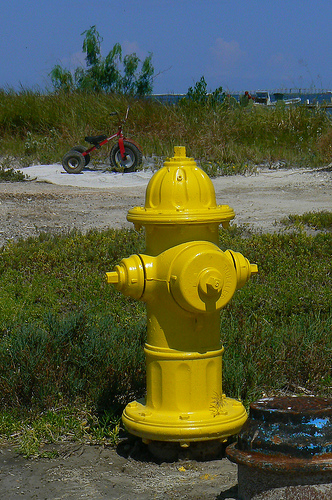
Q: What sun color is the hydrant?
A: Yellow.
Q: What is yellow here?
A: Fire hydrant.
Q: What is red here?
A: A bicycle.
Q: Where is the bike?
A: On the dirt.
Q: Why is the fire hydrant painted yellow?
A: To make it visible.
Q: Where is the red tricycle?
A: On the path.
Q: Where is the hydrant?
A: In the foreground near the camera.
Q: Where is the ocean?
A: Behind the grasses and trees.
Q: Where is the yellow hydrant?
A: Along the path.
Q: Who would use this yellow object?
A: Firefighters.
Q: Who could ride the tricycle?
A: A child.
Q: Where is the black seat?
A: On the tricycle.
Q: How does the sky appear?
A: Clear and blue.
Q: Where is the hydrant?
A: On concrete.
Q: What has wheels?
A: A tricycle.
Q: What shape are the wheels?
A: Round.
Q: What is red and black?
A: Tricycle.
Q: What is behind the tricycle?
A: Long grass.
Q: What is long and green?
A: The grass.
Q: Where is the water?
A: In the distance.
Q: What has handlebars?
A: The tricycle.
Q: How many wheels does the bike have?
A: 3.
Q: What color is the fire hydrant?
A: Yellow.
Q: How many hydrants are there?
A: 1.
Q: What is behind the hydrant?
A: A tricycle.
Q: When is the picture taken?
A: Daytime.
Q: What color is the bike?
A: Red.